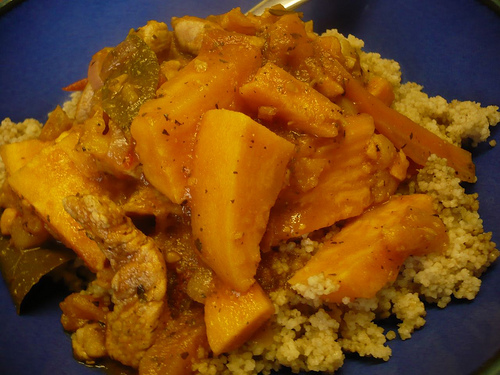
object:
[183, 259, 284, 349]
vegetable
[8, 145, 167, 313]
vegetable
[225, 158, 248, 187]
grain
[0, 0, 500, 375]
meal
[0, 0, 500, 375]
food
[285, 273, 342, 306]
rice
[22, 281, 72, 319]
shadow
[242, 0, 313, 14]
handle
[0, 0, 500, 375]
plate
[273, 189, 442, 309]
vegetable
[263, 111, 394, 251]
vegetable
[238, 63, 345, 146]
vegetable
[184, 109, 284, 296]
vegetable